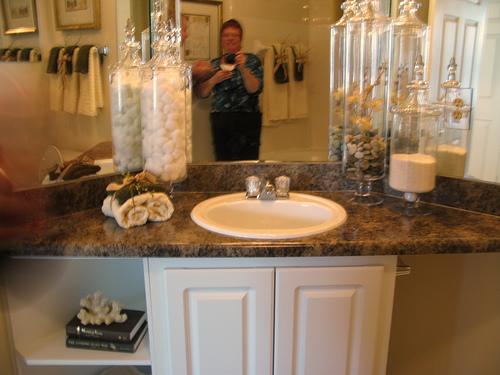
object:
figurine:
[77, 292, 128, 325]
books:
[65, 306, 148, 354]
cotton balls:
[138, 69, 192, 180]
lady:
[193, 18, 264, 160]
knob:
[275, 175, 290, 197]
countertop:
[1, 189, 498, 246]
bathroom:
[0, 0, 500, 375]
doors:
[149, 256, 383, 375]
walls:
[176, 0, 345, 132]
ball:
[160, 91, 175, 104]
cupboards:
[163, 267, 383, 375]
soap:
[389, 154, 437, 193]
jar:
[391, 54, 444, 194]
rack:
[49, 45, 98, 52]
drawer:
[272, 261, 396, 375]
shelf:
[7, 260, 154, 365]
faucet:
[258, 178, 279, 201]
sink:
[188, 190, 346, 241]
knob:
[245, 176, 261, 197]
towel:
[101, 171, 171, 229]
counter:
[0, 188, 496, 257]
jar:
[138, 20, 193, 183]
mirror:
[0, 0, 500, 190]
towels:
[44, 44, 104, 116]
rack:
[98, 48, 109, 54]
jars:
[340, 0, 388, 182]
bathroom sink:
[191, 189, 349, 238]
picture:
[5, 3, 34, 33]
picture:
[50, 0, 99, 29]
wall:
[0, 2, 130, 186]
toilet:
[35, 143, 80, 180]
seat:
[37, 146, 65, 166]